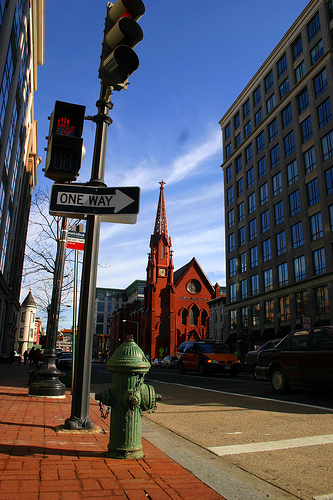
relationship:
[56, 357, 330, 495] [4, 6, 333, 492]
street in city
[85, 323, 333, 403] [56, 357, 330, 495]
traffic on street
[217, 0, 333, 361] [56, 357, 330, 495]
building along street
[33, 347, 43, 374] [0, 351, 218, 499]
person walking on sidewalk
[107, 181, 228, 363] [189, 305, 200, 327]
building has window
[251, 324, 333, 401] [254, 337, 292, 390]
car has rear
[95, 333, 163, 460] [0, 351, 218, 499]
fire hydrant on sidewalk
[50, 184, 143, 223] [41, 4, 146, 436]
sign attatched to pole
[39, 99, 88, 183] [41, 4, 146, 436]
light attached to pole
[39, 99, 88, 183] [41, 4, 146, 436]
light on top of pole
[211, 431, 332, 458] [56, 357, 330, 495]
line painted on street